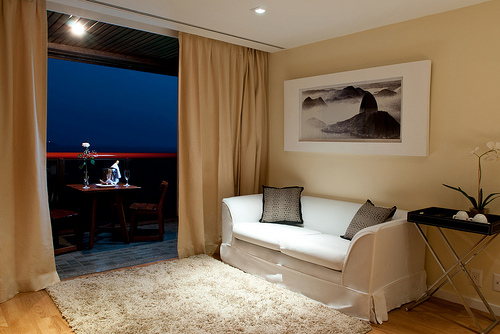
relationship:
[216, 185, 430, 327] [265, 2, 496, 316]
couch against wall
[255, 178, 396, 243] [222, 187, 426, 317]
pillows on couch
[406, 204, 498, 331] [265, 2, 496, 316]
stand against wall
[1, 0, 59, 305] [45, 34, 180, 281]
curtain to terrace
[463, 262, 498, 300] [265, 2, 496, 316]
outlets on wall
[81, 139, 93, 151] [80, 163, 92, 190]
rose in vase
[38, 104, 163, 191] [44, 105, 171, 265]
sign on pole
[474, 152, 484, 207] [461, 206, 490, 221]
stem in planter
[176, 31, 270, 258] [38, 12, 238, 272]
curtains on door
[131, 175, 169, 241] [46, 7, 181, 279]
chair in room